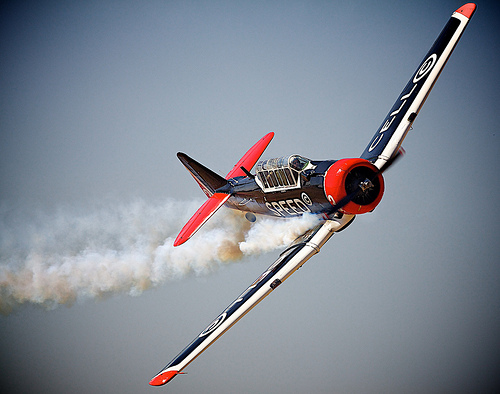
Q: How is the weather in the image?
A: It is cloudless.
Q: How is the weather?
A: It is cloudless.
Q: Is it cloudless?
A: Yes, it is cloudless.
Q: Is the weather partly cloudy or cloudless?
A: It is cloudless.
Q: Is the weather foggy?
A: No, it is cloudless.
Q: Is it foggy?
A: No, it is cloudless.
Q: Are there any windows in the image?
A: Yes, there are windows.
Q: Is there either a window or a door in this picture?
A: Yes, there are windows.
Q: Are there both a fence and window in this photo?
A: No, there are windows but no fences.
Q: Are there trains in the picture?
A: No, there are no trains.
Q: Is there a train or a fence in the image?
A: No, there are no trains or fences.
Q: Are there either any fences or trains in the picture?
A: No, there are no trains or fences.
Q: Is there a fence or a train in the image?
A: No, there are no trains or fences.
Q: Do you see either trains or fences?
A: No, there are no trains or fences.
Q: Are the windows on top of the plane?
A: Yes, the windows are on top of the plane.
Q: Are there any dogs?
A: No, there are no dogs.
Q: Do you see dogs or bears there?
A: No, there are no dogs or bears.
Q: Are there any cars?
A: No, there are no cars.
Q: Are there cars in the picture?
A: No, there are no cars.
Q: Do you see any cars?
A: No, there are no cars.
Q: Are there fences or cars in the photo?
A: No, there are no cars or fences.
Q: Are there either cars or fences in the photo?
A: No, there are no cars or fences.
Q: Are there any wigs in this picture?
A: No, there are no wigs.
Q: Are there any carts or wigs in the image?
A: No, there are no wigs or carts.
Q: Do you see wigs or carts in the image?
A: No, there are no wigs or carts.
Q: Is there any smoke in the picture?
A: Yes, there is smoke.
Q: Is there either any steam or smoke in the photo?
A: Yes, there is smoke.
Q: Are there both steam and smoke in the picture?
A: No, there is smoke but no steam.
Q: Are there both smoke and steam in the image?
A: No, there is smoke but no steam.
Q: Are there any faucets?
A: No, there are no faucets.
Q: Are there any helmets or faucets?
A: No, there are no faucets or helmets.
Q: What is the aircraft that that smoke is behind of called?
A: The aircraft is an airplane.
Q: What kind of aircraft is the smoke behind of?
A: The smoke is behind the plane.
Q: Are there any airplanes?
A: Yes, there is an airplane.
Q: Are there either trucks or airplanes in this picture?
A: Yes, there is an airplane.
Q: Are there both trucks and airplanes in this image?
A: No, there is an airplane but no trucks.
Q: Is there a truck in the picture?
A: No, there are no trucks.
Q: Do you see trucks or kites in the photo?
A: No, there are no trucks or kites.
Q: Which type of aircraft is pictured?
A: The aircraft is an airplane.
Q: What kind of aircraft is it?
A: The aircraft is an airplane.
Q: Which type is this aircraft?
A: This is an airplane.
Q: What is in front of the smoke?
A: The plane is in front of the smoke.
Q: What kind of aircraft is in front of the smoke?
A: The aircraft is an airplane.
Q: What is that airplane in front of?
A: The airplane is in front of the smoke.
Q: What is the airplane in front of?
A: The airplane is in front of the smoke.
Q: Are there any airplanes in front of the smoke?
A: Yes, there is an airplane in front of the smoke.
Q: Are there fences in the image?
A: No, there are no fences.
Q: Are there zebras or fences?
A: No, there are no fences or zebras.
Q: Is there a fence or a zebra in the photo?
A: No, there are no fences or zebras.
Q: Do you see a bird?
A: No, there are no birds.